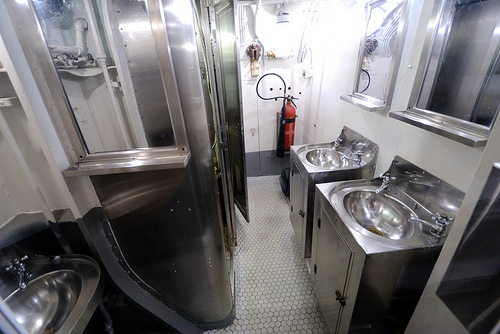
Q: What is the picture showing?
A: It is showing a bathroom.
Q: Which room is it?
A: It is a bathroom.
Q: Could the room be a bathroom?
A: Yes, it is a bathroom.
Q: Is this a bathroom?
A: Yes, it is a bathroom.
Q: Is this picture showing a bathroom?
A: Yes, it is showing a bathroom.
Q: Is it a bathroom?
A: Yes, it is a bathroom.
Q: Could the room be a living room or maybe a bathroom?
A: It is a bathroom.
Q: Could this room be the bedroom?
A: No, it is the bathroom.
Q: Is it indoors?
A: Yes, it is indoors.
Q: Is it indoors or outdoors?
A: It is indoors.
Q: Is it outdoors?
A: No, it is indoors.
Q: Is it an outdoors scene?
A: No, it is indoors.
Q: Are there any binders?
A: No, there are no binders.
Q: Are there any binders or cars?
A: No, there are no binders or cars.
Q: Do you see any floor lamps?
A: No, there are no floor lamps.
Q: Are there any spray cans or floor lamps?
A: No, there are no floor lamps or spray cans.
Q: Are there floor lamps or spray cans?
A: No, there are no floor lamps or spray cans.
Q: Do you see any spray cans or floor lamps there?
A: No, there are no floor lamps or spray cans.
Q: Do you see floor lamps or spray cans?
A: No, there are no floor lamps or spray cans.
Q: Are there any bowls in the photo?
A: No, there are no bowls.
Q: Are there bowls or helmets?
A: No, there are no bowls or helmets.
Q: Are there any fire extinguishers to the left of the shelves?
A: Yes, there is a fire extinguisher to the left of the shelves.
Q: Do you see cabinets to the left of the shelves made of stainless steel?
A: No, there is a fire extinguisher to the left of the shelves.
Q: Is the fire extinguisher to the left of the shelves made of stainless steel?
A: Yes, the fire extinguisher is to the left of the shelves.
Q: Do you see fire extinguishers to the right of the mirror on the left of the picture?
A: Yes, there is a fire extinguisher to the right of the mirror.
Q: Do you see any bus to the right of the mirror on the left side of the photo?
A: No, there is a fire extinguisher to the right of the mirror.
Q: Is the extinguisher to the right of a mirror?
A: Yes, the extinguisher is to the right of a mirror.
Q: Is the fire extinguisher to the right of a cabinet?
A: No, the fire extinguisher is to the right of a mirror.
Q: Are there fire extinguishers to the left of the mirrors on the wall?
A: Yes, there is a fire extinguisher to the left of the mirrors.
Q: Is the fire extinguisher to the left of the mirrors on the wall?
A: Yes, the fire extinguisher is to the left of the mirrors.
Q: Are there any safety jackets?
A: No, there are no safety jackets.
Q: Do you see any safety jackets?
A: No, there are no safety jackets.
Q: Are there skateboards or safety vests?
A: No, there are no safety vests or skateboards.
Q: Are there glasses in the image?
A: No, there are no glasses.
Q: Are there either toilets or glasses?
A: No, there are no glasses or toilets.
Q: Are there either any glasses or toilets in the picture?
A: No, there are no glasses or toilets.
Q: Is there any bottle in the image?
A: No, there are no bottles.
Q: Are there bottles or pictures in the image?
A: No, there are no bottles or pictures.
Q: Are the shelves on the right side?
A: Yes, the shelves are on the right of the image.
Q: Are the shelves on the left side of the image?
A: No, the shelves are on the right of the image.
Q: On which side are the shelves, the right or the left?
A: The shelves are on the right of the image.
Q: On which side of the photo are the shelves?
A: The shelves are on the right of the image.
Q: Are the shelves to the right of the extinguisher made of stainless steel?
A: Yes, the shelves are made of stainless steel.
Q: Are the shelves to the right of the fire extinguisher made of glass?
A: No, the shelves are made of stainless steel.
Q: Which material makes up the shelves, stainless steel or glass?
A: The shelves are made of stainless steel.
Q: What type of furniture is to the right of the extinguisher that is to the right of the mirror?
A: The pieces of furniture are shelves.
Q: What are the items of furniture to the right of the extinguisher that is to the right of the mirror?
A: The pieces of furniture are shelves.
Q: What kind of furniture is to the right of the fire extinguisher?
A: The pieces of furniture are shelves.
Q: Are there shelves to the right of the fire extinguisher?
A: Yes, there are shelves to the right of the fire extinguisher.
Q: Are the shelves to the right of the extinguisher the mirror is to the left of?
A: Yes, the shelves are to the right of the fire extinguisher.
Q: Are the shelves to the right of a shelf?
A: No, the shelves are to the right of the fire extinguisher.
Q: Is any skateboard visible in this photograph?
A: No, there are no skateboards.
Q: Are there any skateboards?
A: No, there are no skateboards.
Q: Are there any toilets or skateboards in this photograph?
A: No, there are no skateboards or toilets.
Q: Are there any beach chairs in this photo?
A: No, there are no beach chairs.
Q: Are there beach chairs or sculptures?
A: No, there are no beach chairs or sculptures.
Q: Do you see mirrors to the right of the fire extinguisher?
A: Yes, there are mirrors to the right of the fire extinguisher.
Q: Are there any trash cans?
A: No, there are no trash cans.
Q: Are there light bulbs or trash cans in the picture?
A: No, there are no trash cans or light bulbs.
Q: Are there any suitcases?
A: No, there are no suitcases.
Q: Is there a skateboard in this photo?
A: No, there are no skateboards.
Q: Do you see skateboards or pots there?
A: No, there are no skateboards or pots.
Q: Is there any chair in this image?
A: No, there are no chairs.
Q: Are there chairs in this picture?
A: No, there are no chairs.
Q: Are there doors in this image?
A: Yes, there is a door.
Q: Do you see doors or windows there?
A: Yes, there is a door.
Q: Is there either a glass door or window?
A: Yes, there is a glass door.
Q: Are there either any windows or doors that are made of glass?
A: Yes, the door is made of glass.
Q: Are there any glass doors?
A: Yes, there is a door that is made of glass.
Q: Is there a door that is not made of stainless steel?
A: Yes, there is a door that is made of glass.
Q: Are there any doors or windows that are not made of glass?
A: No, there is a door but it is made of glass.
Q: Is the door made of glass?
A: Yes, the door is made of glass.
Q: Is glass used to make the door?
A: Yes, the door is made of glass.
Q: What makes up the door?
A: The door is made of glass.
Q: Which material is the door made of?
A: The door is made of glass.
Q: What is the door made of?
A: The door is made of glass.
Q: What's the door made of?
A: The door is made of glass.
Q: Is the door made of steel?
A: No, the door is made of glass.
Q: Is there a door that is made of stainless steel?
A: No, there is a door but it is made of glass.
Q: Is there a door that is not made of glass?
A: No, there is a door but it is made of glass.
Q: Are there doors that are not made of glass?
A: No, there is a door but it is made of glass.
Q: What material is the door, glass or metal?
A: The door is made of glass.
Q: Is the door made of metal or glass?
A: The door is made of glass.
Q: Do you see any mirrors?
A: Yes, there is a mirror.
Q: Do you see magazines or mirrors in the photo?
A: Yes, there is a mirror.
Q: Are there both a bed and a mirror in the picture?
A: No, there is a mirror but no beds.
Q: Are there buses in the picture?
A: No, there are no buses.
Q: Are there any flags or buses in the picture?
A: No, there are no buses or flags.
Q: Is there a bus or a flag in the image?
A: No, there are no buses or flags.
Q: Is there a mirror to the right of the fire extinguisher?
A: Yes, there is a mirror to the right of the fire extinguisher.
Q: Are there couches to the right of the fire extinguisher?
A: No, there is a mirror to the right of the fire extinguisher.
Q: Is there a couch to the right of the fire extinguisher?
A: No, there is a mirror to the right of the fire extinguisher.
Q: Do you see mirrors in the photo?
A: Yes, there is a mirror.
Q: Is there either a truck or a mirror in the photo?
A: Yes, there is a mirror.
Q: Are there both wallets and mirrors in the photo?
A: No, there is a mirror but no wallets.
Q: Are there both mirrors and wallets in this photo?
A: No, there is a mirror but no wallets.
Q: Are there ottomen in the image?
A: No, there are no ottomen.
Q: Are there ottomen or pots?
A: No, there are no ottomen or pots.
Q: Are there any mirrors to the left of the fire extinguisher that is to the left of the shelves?
A: Yes, there is a mirror to the left of the fire extinguisher.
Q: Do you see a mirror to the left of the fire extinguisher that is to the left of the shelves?
A: Yes, there is a mirror to the left of the fire extinguisher.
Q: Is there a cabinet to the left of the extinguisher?
A: No, there is a mirror to the left of the extinguisher.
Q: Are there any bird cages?
A: No, there are no bird cages.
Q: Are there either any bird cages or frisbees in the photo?
A: No, there are no bird cages or frisbees.